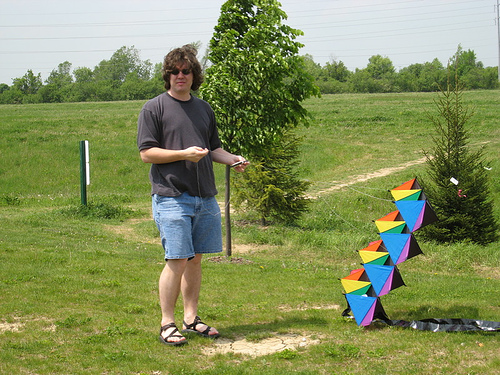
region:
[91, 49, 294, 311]
man is posed for a picture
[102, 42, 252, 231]
man is wearing sunglasses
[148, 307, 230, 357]
man is wearing sandal shoies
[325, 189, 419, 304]
the kite is multicolored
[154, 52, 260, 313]
man holding rope of a kite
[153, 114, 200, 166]
the t shirt is black in color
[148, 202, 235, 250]
short is blue in color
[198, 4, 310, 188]
trees are green in color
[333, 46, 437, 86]
trees are at the egd of the picture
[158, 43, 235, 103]
face of the person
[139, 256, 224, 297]
legs of the person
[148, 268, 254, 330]
legs of the person are white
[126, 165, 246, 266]
a person wearing short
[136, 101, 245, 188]
a person wearing t shirt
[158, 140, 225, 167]
hand of the person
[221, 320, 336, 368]
a white sand on ground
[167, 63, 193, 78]
dark black sunglasses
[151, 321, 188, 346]
a man's sandal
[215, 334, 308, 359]
a section of brown dirt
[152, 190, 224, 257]
a man's blue jean shorts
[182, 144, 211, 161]
the hand of a man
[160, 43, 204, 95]
a man's brown curly hair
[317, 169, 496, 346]
a large colorful kite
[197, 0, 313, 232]
a tall green tree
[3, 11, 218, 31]
a long electrical power line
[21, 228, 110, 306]
a section of green grass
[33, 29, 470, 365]
a man and his kite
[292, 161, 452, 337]
this kite has rainbow colors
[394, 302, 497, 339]
the kite has a tail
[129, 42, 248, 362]
this guy looks content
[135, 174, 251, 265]
he has on blue jeans shorts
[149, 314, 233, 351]
he is wearing sandals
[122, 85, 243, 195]
he has on a gray shirt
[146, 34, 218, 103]
the man has on glasses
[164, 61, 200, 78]
the man has on sun glasses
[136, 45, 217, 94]
his hair is wild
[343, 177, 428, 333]
the man holds a kite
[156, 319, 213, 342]
the man wears sandals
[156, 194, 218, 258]
the man wears denim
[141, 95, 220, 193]
the man wears black shirt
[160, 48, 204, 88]
the man has long hair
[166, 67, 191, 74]
the man wears glasses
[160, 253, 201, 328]
the man has white legs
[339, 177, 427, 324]
the kite is colorful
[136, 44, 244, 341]
the man stands on the grass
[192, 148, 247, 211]
the man holds the string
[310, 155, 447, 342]
kite on the ground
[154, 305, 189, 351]
sandal on the foot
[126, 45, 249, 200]
black t-shirt on the man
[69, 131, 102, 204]
sign in the ground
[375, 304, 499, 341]
black tails on the kite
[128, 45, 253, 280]
blue jean shorts on the man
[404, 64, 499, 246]
tree near the kite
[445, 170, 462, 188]
white tag on the tree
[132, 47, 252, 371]
man in a field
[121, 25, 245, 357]
man in some sandals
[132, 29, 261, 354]
man in jean shorts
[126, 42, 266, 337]
man in a t-shirt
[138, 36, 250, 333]
man in a black t-shirt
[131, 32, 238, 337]
man in blue jean shorts